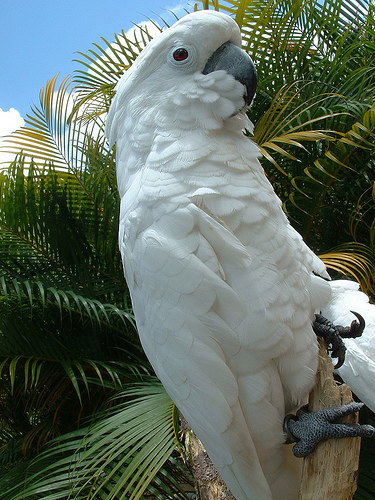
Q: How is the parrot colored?
A: White.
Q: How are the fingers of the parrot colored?
A: Black.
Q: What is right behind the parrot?
A: Palm tree.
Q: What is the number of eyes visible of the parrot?
A: One.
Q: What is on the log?
A: A white bird.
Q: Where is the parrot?
A: On a log.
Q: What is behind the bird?
A: Ferns.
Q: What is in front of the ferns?
A: A parrot.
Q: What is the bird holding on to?
A: A log.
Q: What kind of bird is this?
A: A parrot.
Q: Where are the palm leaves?
A: Behind the bird.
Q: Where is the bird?
A: On top of a log.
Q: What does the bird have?
A: Wings.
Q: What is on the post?
A: Bird.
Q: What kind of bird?
A: Parrot.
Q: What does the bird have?
A: Eye.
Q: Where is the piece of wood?
A: Under the bird.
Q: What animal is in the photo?
A: A bird.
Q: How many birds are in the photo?
A: One.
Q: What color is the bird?
A: White.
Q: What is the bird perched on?
A: Wood.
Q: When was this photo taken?
A: During the daytime.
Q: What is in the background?
A: Trees and the sky.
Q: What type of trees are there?
A: Palm trees.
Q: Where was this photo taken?
A: In a tree.